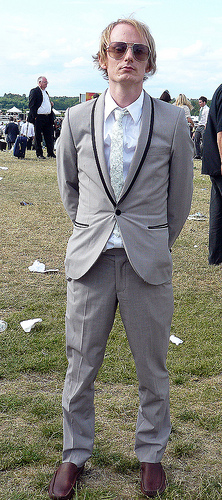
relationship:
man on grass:
[47, 11, 194, 498] [1, 148, 220, 496]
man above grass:
[47, 11, 194, 498] [1, 148, 220, 496]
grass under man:
[1, 148, 220, 496] [47, 11, 194, 498]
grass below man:
[1, 148, 220, 496] [47, 11, 194, 498]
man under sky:
[47, 11, 194, 498] [2, 2, 220, 88]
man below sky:
[47, 11, 194, 498] [2, 2, 220, 88]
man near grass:
[47, 11, 194, 498] [1, 148, 220, 496]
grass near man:
[1, 148, 220, 496] [47, 11, 194, 498]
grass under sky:
[1, 148, 220, 496] [2, 2, 220, 88]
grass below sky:
[1, 148, 220, 496] [2, 2, 220, 88]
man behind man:
[28, 74, 70, 153] [47, 11, 194, 498]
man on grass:
[28, 74, 70, 153] [1, 148, 220, 496]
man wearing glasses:
[47, 11, 194, 498] [110, 44, 151, 63]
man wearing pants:
[47, 11, 194, 498] [60, 245, 175, 468]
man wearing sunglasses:
[47, 11, 194, 498] [103, 40, 152, 62]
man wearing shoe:
[47, 11, 194, 498] [47, 460, 85, 498]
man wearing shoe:
[47, 11, 194, 498] [138, 459, 167, 496]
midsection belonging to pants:
[65, 247, 175, 303] [60, 245, 175, 468]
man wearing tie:
[47, 11, 194, 498] [111, 107, 129, 236]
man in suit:
[28, 77, 58, 156] [25, 68, 56, 156]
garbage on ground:
[0, 202, 209, 361] [0, 151, 222, 498]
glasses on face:
[108, 41, 151, 63] [102, 20, 147, 81]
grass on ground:
[1, 148, 220, 496] [4, 151, 219, 383]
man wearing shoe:
[49, 20, 195, 500] [47, 460, 79, 500]